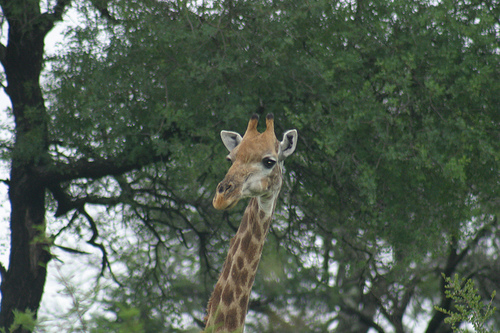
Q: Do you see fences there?
A: No, there are no fences.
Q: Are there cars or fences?
A: No, there are no fences or cars.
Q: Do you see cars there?
A: No, there are no cars.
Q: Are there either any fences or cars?
A: No, there are no cars or fences.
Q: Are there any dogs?
A: No, there are no dogs.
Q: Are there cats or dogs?
A: No, there are no dogs or cats.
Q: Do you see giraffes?
A: Yes, there is a giraffe.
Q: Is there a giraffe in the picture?
A: Yes, there is a giraffe.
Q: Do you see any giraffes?
A: Yes, there is a giraffe.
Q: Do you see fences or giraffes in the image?
A: Yes, there is a giraffe.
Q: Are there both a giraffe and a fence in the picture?
A: No, there is a giraffe but no fences.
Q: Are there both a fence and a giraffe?
A: No, there is a giraffe but no fences.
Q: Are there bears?
A: No, there are no bears.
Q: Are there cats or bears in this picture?
A: No, there are no bears or cats.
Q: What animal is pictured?
A: The animal is a giraffe.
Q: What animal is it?
A: The animal is a giraffe.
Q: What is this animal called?
A: This is a giraffe.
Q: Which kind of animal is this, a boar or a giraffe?
A: This is a giraffe.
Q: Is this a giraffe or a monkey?
A: This is a giraffe.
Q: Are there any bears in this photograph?
A: No, there are no bears.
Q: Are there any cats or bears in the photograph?
A: No, there are no bears or cats.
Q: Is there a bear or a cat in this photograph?
A: No, there are no bears or cats.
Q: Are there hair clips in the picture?
A: No, there are no hair clips.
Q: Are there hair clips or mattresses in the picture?
A: No, there are no hair clips or mattresses.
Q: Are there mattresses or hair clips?
A: No, there are no hair clips or mattresses.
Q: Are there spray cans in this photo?
A: No, there are no spray cans.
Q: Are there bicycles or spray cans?
A: No, there are no spray cans or bicycles.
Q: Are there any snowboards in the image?
A: No, there are no snowboards.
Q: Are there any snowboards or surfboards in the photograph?
A: No, there are no snowboards or surfboards.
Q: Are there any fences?
A: No, there are no fences.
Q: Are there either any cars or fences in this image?
A: No, there are no fences or cars.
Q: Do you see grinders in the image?
A: No, there are no grinders.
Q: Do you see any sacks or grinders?
A: No, there are no grinders or sacks.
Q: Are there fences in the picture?
A: No, there are no fences.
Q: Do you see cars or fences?
A: No, there are no fences or cars.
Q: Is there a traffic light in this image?
A: No, there are no traffic lights.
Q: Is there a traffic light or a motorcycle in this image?
A: No, there are no traffic lights or motorcycles.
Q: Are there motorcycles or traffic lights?
A: No, there are no traffic lights or motorcycles.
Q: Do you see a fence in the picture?
A: No, there are no fences.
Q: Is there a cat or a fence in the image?
A: No, there are no fences or cats.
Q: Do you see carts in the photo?
A: No, there are no carts.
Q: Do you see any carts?
A: No, there are no carts.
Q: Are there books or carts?
A: No, there are no carts or books.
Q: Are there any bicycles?
A: No, there are no bicycles.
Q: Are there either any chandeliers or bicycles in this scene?
A: No, there are no bicycles or chandeliers.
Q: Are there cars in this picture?
A: No, there are no cars.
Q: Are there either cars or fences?
A: No, there are no cars or fences.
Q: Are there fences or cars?
A: No, there are no cars or fences.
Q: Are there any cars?
A: No, there are no cars.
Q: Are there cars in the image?
A: No, there are no cars.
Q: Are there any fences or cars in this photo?
A: No, there are no cars or fences.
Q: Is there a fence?
A: No, there are no fences.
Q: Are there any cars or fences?
A: No, there are no fences or cars.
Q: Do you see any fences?
A: No, there are no fences.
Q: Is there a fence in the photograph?
A: No, there are no fences.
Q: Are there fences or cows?
A: No, there are no fences or cows.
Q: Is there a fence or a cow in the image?
A: No, there are no fences or cows.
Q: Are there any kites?
A: No, there are no kites.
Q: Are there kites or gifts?
A: No, there are no kites or gifts.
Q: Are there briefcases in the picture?
A: No, there are no briefcases.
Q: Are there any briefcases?
A: No, there are no briefcases.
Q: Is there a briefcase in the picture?
A: No, there are no briefcases.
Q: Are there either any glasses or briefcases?
A: No, there are no briefcases or glasses.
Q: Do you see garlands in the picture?
A: No, there are no garlands.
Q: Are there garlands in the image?
A: No, there are no garlands.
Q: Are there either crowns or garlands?
A: No, there are no garlands or crowns.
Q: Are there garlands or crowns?
A: No, there are no garlands or crowns.